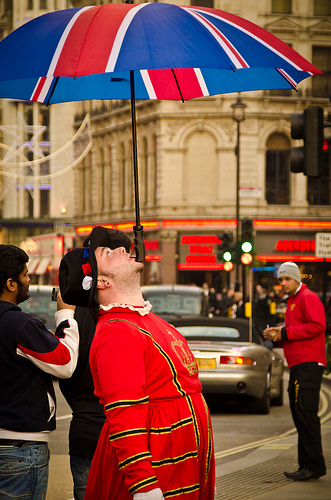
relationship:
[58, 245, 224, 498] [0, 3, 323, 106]
man balancing umbrella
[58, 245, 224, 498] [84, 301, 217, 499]
man wearing jacket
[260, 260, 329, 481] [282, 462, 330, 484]
man wearing boot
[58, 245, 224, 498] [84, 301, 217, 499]
man wearing outfit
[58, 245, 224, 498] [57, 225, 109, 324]
man wearing hat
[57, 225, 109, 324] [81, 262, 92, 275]
hat has red object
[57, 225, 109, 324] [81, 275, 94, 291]
hat has white object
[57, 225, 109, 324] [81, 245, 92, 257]
hat has blue object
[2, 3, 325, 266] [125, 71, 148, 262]
umbrella has handle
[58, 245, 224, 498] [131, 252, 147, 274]
man has chin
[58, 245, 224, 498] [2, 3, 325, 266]
man holding umbrella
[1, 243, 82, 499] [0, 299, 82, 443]
man wearing jacket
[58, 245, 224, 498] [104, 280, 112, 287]
man wearing earring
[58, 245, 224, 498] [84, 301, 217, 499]
man wearing dress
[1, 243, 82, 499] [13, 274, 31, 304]
man has beard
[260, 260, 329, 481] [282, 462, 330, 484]
man wearing shoes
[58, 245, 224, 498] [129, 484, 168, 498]
man wearing glove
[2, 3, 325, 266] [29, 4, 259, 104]
umbrella like union jack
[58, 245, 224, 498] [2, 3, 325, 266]
man balancing umbrella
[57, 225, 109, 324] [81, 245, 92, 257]
hat has blue flower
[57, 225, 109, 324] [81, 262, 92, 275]
hat has flower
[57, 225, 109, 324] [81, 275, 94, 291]
hat has flower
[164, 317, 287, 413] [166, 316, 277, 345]
convertible has soft top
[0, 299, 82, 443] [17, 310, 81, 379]
jacket has sleeve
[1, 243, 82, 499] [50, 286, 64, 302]
man holding camera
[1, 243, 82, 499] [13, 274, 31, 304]
man sporting beard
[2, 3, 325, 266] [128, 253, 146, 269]
umbrella held on man's mouth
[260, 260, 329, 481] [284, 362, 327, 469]
man wearing pants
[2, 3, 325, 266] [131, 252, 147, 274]
umbrella balancing on chin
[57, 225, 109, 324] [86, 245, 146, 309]
hat worn on mans head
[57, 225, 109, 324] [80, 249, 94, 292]
hat has flowers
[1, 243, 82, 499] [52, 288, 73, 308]
man taking picture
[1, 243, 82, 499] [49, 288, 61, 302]
man has phone